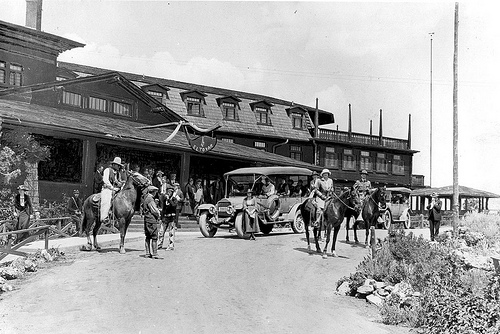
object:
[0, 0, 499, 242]
building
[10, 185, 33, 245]
people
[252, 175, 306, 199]
people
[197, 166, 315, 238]
car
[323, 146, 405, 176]
windows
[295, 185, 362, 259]
horse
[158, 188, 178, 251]
person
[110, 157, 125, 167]
hat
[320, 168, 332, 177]
hat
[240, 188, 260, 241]
person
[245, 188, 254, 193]
hat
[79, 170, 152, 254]
horse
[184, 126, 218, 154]
plane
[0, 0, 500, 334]
picture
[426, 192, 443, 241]
man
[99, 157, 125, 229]
man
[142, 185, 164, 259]
man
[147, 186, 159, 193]
cap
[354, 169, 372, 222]
person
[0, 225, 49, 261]
rail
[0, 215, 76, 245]
rail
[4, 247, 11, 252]
wood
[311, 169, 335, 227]
person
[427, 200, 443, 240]
suit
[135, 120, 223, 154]
sign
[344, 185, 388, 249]
horse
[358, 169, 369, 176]
hat